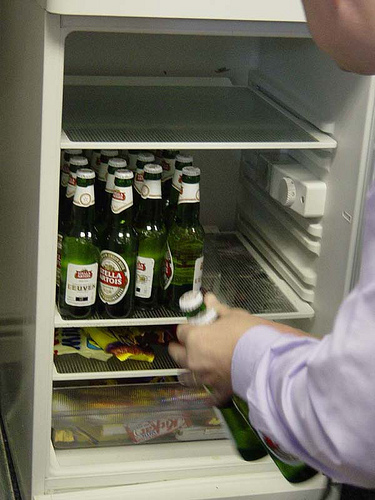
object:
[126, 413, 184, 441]
kitkat bar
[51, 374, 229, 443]
drawer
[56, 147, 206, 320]
beer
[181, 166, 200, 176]
cap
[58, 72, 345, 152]
shelf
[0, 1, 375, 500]
fridge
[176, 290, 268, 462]
beer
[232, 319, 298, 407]
cufflink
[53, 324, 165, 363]
food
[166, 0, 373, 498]
man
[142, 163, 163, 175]
cap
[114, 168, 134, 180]
cap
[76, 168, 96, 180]
cap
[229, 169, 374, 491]
shirt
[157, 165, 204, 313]
bottle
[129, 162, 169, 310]
bottle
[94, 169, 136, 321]
bottle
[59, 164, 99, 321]
bottle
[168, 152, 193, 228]
bottle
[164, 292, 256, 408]
hand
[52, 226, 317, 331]
shelf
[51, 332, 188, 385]
shelf